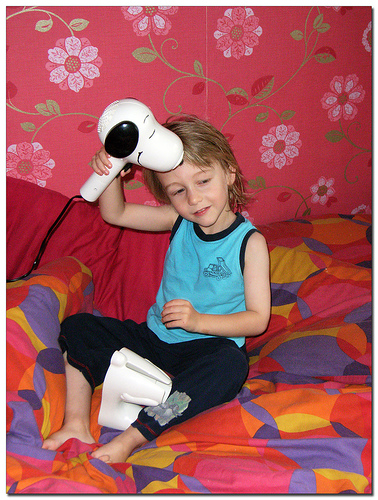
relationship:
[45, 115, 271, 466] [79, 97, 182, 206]
child holding blow dryer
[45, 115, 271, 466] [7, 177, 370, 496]
child on bed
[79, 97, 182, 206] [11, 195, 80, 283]
blow dryer has wire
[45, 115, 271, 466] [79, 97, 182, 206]
child has blow dryer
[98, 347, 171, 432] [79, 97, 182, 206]
holder for blow dryer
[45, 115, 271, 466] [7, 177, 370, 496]
child sitting on bed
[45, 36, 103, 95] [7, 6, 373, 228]
flower on wallpaper